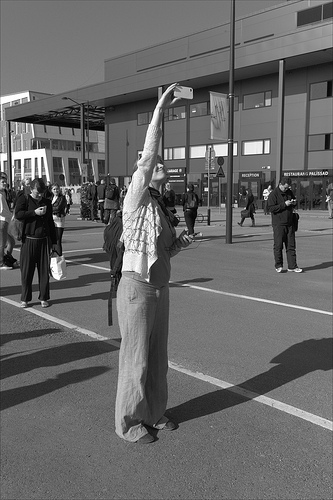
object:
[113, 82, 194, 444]
person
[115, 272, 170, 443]
pants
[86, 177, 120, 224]
people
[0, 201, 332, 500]
road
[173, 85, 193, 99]
phone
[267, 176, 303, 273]
man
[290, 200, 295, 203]
phone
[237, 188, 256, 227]
person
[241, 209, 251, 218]
bag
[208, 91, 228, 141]
banner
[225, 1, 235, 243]
pole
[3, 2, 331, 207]
building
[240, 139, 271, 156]
windows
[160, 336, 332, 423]
shadow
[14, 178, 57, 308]
woman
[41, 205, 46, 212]
phone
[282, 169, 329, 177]
sign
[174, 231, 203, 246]
electronics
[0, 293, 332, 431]
stripes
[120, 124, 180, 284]
sweater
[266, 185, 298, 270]
clothes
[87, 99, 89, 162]
column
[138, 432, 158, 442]
shoe